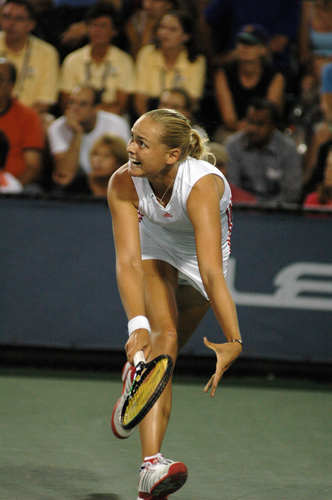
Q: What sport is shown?
A: Tennis.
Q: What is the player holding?
A: Tennis raquet.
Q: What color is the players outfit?
A: White, red.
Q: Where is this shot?
A: Tennis court.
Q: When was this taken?
A: Night time.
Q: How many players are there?
A: 1.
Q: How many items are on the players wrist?
A: 2.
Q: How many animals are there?
A: 0.